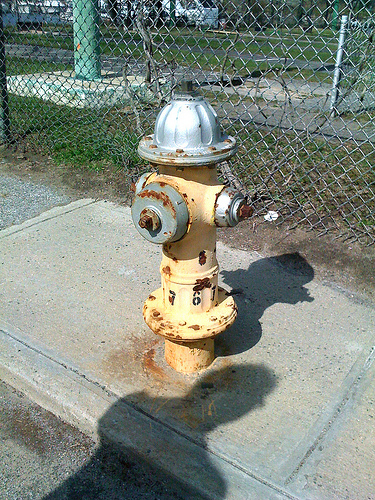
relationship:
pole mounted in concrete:
[72, 0, 101, 80] [29, 183, 108, 284]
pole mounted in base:
[70, 0, 101, 80] [5, 67, 174, 109]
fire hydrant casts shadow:
[129, 79, 254, 374] [213, 250, 313, 359]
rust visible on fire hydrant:
[194, 245, 208, 270] [124, 76, 261, 372]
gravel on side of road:
[6, 402, 142, 489] [0, 376, 211, 499]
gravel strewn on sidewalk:
[1, 167, 373, 498] [1, 168, 373, 498]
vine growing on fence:
[137, 16, 157, 75] [0, 2, 373, 237]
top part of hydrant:
[136, 77, 234, 167] [104, 68, 265, 362]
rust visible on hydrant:
[150, 257, 171, 278] [129, 78, 255, 373]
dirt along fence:
[1, 148, 373, 297] [0, 2, 373, 237]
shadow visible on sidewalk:
[25, 358, 281, 498] [1, 168, 373, 498]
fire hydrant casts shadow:
[129, 79, 254, 374] [179, 257, 329, 337]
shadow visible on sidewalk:
[179, 257, 329, 337] [1, 168, 373, 498]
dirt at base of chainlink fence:
[1, 148, 373, 297] [0, 1, 373, 247]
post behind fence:
[327, 13, 347, 116] [0, 2, 373, 237]